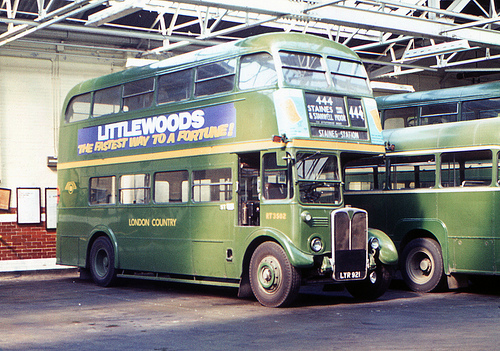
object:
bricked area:
[0, 221, 56, 259]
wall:
[1, 52, 122, 259]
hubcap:
[255, 255, 282, 295]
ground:
[321, 316, 417, 351]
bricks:
[0, 221, 57, 260]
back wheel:
[83, 232, 117, 288]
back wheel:
[398, 238, 444, 294]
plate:
[337, 269, 363, 279]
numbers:
[336, 270, 365, 281]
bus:
[338, 116, 500, 295]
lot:
[0, 264, 499, 349]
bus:
[373, 79, 500, 131]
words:
[127, 218, 177, 227]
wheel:
[249, 239, 302, 308]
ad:
[75, 100, 239, 155]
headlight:
[310, 237, 323, 251]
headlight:
[369, 236, 379, 250]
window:
[194, 54, 237, 81]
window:
[195, 74, 232, 97]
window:
[157, 65, 189, 103]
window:
[121, 75, 154, 97]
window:
[121, 91, 152, 113]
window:
[92, 83, 123, 118]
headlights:
[368, 271, 377, 285]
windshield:
[294, 152, 344, 203]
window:
[438, 148, 493, 187]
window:
[342, 153, 433, 192]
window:
[190, 171, 229, 204]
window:
[150, 170, 190, 202]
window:
[92, 84, 119, 117]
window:
[236, 149, 263, 226]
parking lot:
[0, 265, 499, 350]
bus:
[51, 30, 403, 308]